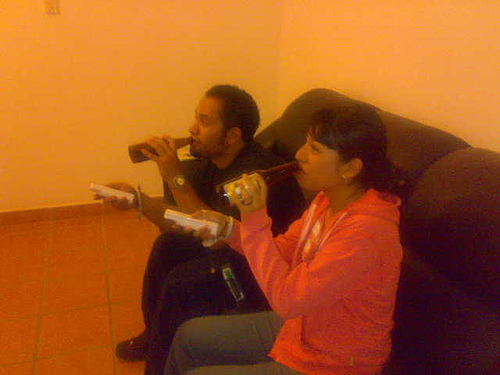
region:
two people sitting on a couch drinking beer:
[112, 83, 404, 373]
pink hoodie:
[227, 184, 405, 371]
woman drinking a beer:
[213, 98, 412, 372]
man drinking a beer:
[125, 83, 285, 309]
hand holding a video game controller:
[157, 201, 229, 250]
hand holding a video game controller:
[86, 176, 144, 218]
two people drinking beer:
[120, 80, 403, 216]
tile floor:
[3, 212, 147, 372]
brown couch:
[294, 72, 496, 370]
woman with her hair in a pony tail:
[289, 99, 409, 204]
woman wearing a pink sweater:
[215, 95, 409, 365]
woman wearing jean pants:
[206, 98, 397, 366]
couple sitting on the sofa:
[139, 71, 399, 362]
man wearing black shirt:
[112, 77, 253, 307]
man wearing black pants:
[124, 83, 272, 301]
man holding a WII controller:
[90, 66, 255, 298]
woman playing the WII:
[175, 112, 397, 364]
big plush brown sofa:
[234, 85, 492, 357]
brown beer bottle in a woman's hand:
[212, 154, 299, 211]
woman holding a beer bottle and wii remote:
[161, 101, 407, 373]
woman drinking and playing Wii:
[161, 103, 408, 374]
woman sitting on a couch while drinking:
[161, 104, 405, 372]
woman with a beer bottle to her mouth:
[161, 100, 416, 374]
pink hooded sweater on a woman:
[218, 186, 406, 373]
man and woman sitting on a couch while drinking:
[84, 78, 499, 372]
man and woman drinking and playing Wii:
[88, 81, 499, 373]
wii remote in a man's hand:
[83, 180, 136, 205]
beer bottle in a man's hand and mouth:
[126, 128, 194, 164]